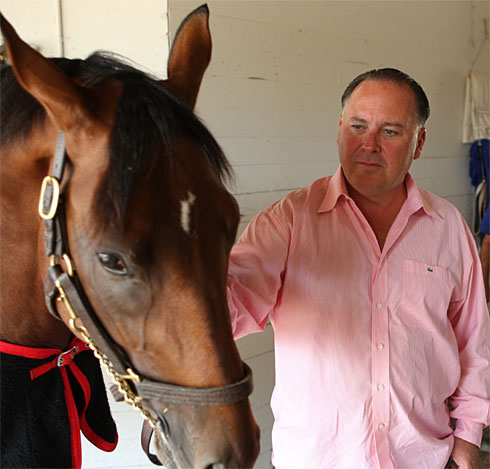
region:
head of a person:
[329, 63, 457, 225]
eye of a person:
[338, 114, 367, 149]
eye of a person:
[378, 121, 408, 140]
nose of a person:
[358, 138, 390, 157]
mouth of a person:
[345, 158, 389, 175]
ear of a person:
[409, 121, 439, 163]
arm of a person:
[444, 316, 488, 408]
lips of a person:
[355, 158, 389, 169]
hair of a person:
[375, 63, 417, 77]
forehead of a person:
[342, 79, 410, 115]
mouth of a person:
[348, 149, 381, 179]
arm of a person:
[429, 287, 487, 395]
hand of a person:
[453, 425, 488, 467]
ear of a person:
[395, 117, 443, 182]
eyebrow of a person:
[383, 121, 405, 127]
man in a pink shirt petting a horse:
[1, 0, 489, 466]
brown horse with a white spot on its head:
[4, 2, 262, 468]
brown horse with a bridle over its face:
[4, 1, 264, 468]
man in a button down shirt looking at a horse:
[2, 3, 487, 468]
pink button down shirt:
[227, 166, 489, 468]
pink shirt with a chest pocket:
[232, 164, 489, 467]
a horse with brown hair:
[0, 1, 267, 468]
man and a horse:
[0, 1, 489, 467]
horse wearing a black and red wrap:
[2, 0, 263, 466]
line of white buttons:
[370, 294, 391, 432]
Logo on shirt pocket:
[423, 266, 432, 274]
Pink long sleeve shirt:
[224, 165, 489, 468]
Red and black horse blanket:
[1, 334, 118, 468]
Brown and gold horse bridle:
[39, 128, 253, 468]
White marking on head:
[174, 186, 198, 235]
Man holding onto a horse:
[226, 68, 489, 468]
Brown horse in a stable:
[2, 0, 258, 467]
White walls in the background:
[2, 1, 489, 467]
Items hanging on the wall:
[463, 19, 488, 254]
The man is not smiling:
[333, 66, 431, 199]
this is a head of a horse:
[0, 33, 289, 462]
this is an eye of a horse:
[74, 229, 131, 287]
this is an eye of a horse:
[224, 202, 253, 259]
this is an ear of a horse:
[0, 17, 69, 127]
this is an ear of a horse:
[157, 0, 227, 96]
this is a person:
[239, 67, 486, 467]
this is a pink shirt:
[237, 194, 485, 464]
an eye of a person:
[377, 116, 407, 143]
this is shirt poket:
[395, 257, 456, 335]